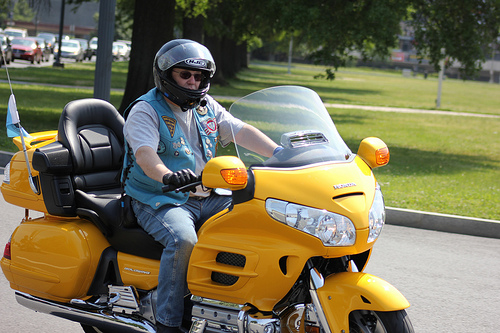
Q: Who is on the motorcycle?
A: The man.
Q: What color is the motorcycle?
A: Yellow.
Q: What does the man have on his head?
A: A helmet.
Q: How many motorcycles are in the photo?
A: One.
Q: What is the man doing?
A: Riding the motorcycle.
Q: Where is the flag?
A: At the rear of the motorcycle.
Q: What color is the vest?
A: Blue.